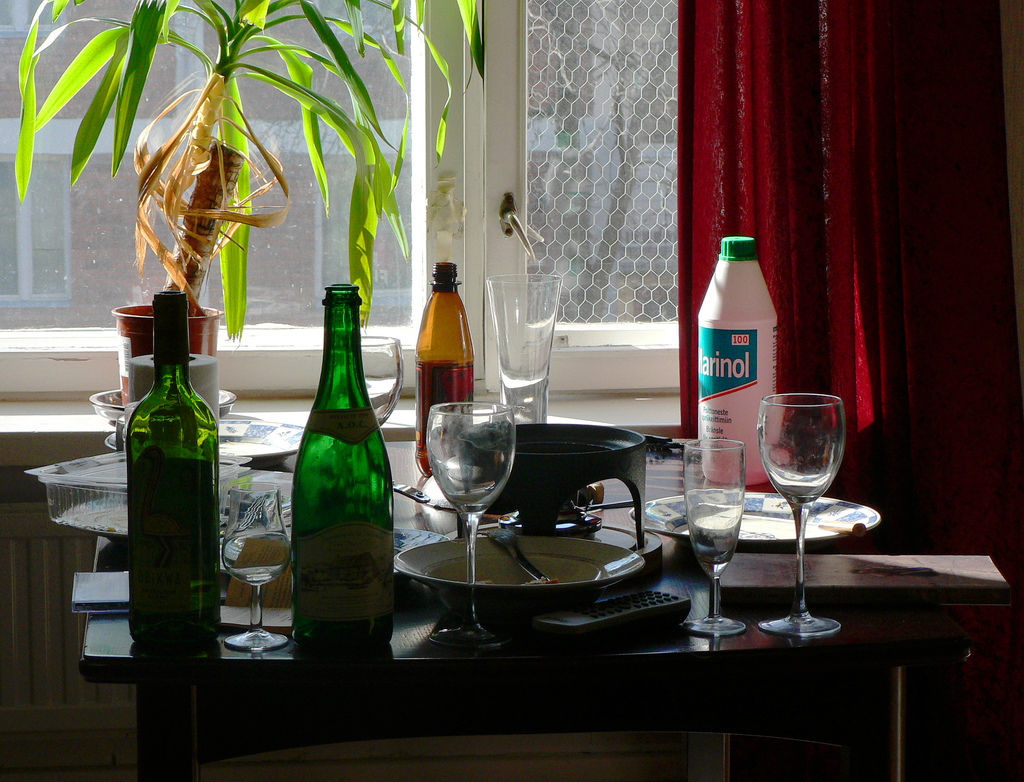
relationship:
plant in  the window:
[34, 3, 456, 287] [286, 214, 308, 279]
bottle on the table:
[265, 273, 387, 695] [565, 623, 643, 658]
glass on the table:
[414, 393, 520, 659] [570, 662, 674, 730]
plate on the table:
[751, 495, 780, 543] [561, 636, 670, 678]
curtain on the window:
[674, 0, 1022, 777] [75, 212, 140, 286]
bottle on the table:
[407, 269, 474, 410] [868, 549, 942, 614]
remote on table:
[518, 572, 704, 659] [0, 460, 1024, 779]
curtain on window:
[674, 0, 1022, 777] [0, 0, 1018, 404]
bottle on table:
[693, 233, 781, 487] [65, 480, 979, 774]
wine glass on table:
[752, 384, 854, 640] [78, 490, 975, 743]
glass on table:
[670, 432, 751, 640] [65, 480, 979, 774]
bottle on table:
[285, 273, 408, 702] [73, 451, 981, 773]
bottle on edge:
[115, 283, 228, 655] [74, 626, 993, 685]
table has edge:
[0, 460, 1024, 779] [74, 626, 993, 685]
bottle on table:
[115, 283, 228, 655] [0, 460, 1024, 779]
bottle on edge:
[285, 273, 408, 702] [74, 626, 993, 685]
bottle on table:
[285, 273, 408, 702] [0, 460, 1024, 779]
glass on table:
[415, 393, 521, 659] [65, 480, 979, 774]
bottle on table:
[285, 273, 408, 702] [65, 480, 979, 774]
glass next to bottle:
[415, 393, 521, 659] [285, 273, 408, 702]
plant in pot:
[9, 2, 486, 340] [101, 302, 231, 376]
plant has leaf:
[9, 2, 486, 340] [101, 30, 160, 182]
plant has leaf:
[9, 2, 486, 340] [41, 30, 122, 139]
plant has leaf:
[9, 2, 486, 340] [296, 0, 398, 152]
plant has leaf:
[9, 2, 486, 340] [238, 63, 386, 316]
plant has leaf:
[9, 2, 486, 340] [7, 4, 49, 206]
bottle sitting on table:
[115, 283, 228, 655] [65, 480, 979, 774]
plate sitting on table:
[391, 520, 662, 629] [65, 480, 979, 774]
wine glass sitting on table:
[752, 384, 854, 640] [65, 480, 979, 774]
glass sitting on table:
[488, 264, 571, 422] [73, 451, 981, 773]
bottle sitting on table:
[693, 233, 781, 487] [73, 510, 983, 774]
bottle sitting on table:
[406, 261, 482, 476] [65, 480, 979, 774]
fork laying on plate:
[480, 520, 557, 591] [391, 520, 655, 644]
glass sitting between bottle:
[214, 467, 301, 651] [115, 283, 228, 655]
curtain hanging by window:
[674, 0, 1016, 778] [7, 4, 1010, 780]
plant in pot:
[9, 2, 486, 340] [110, 296, 236, 405]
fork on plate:
[480, 514, 571, 592] [391, 520, 662, 629]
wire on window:
[529, 6, 676, 316] [484, 0, 675, 407]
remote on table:
[527, 587, 691, 639] [65, 480, 979, 774]